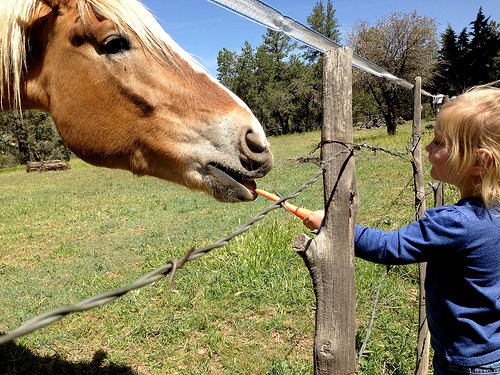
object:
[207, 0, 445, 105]
ribbon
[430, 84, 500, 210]
hair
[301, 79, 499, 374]
child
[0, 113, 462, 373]
pasture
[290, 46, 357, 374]
post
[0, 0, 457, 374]
fence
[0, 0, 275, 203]
horse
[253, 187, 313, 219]
carrot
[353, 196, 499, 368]
blue shirt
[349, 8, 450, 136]
trees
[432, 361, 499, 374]
blue jeans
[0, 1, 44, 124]
mane